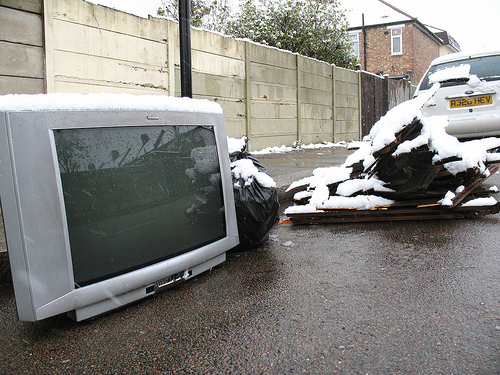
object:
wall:
[410, 22, 439, 88]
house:
[326, 0, 443, 90]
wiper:
[427, 77, 468, 86]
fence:
[0, 0, 417, 155]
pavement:
[0, 147, 500, 374]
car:
[411, 49, 499, 142]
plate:
[448, 93, 492, 109]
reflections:
[52, 125, 227, 288]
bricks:
[369, 47, 376, 49]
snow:
[0, 91, 224, 115]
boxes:
[283, 182, 499, 228]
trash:
[227, 135, 280, 253]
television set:
[0, 107, 241, 325]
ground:
[0, 147, 500, 374]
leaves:
[270, 28, 282, 37]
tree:
[199, 0, 363, 70]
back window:
[417, 53, 500, 91]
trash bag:
[222, 136, 283, 253]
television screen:
[50, 125, 226, 290]